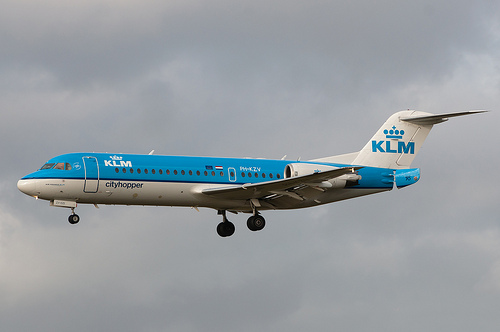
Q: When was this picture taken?
A: At daytime.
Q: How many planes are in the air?
A: One.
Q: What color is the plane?
A: Blue and white.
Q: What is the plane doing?
A: Getting ready to land.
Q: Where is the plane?
A: In the air.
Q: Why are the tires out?
A: To land.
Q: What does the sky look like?
A: Overcast.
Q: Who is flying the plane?
A: The pilot.